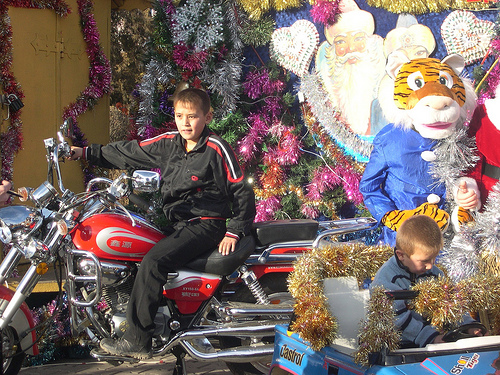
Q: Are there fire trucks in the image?
A: No, there are no fire trucks.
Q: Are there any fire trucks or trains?
A: No, there are no fire trucks or trains.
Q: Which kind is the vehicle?
A: The vehicle is a car.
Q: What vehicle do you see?
A: The vehicle is a car.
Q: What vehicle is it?
A: The vehicle is a car.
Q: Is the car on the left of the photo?
A: No, the car is on the right of the image.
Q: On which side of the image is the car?
A: The car is on the right of the image.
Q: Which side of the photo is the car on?
A: The car is on the right of the image.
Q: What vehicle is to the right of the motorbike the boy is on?
A: The vehicle is a car.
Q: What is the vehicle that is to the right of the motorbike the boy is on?
A: The vehicle is a car.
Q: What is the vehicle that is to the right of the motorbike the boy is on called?
A: The vehicle is a car.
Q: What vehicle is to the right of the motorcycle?
A: The vehicle is a car.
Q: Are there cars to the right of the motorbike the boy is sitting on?
A: Yes, there is a car to the right of the motorbike.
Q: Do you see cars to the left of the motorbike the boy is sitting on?
A: No, the car is to the right of the motorcycle.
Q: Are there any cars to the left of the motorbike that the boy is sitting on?
A: No, the car is to the right of the motorcycle.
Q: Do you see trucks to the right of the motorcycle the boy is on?
A: No, there is a car to the right of the motorbike.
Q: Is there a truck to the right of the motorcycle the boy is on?
A: No, there is a car to the right of the motorbike.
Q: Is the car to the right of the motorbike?
A: Yes, the car is to the right of the motorbike.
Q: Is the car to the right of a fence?
A: No, the car is to the right of the motorbike.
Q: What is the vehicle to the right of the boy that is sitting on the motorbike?
A: The vehicle is a car.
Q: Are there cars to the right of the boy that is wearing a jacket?
A: Yes, there is a car to the right of the boy.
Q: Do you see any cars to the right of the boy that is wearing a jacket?
A: Yes, there is a car to the right of the boy.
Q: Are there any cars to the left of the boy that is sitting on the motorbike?
A: No, the car is to the right of the boy.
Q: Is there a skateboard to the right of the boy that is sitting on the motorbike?
A: No, there is a car to the right of the boy.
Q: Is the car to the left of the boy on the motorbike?
A: No, the car is to the right of the boy.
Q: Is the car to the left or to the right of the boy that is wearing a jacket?
A: The car is to the right of the boy.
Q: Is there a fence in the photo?
A: No, there are no fences.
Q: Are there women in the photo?
A: No, there are no women.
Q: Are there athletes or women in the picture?
A: No, there are no women or athletes.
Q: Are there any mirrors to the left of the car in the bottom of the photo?
A: No, there is a boy to the left of the car.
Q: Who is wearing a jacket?
A: The boy is wearing a jacket.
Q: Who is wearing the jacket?
A: The boy is wearing a jacket.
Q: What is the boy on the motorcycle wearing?
A: The boy is wearing a jacket.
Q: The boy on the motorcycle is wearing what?
A: The boy is wearing a jacket.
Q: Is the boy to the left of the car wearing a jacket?
A: Yes, the boy is wearing a jacket.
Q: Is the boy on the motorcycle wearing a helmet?
A: No, the boy is wearing a jacket.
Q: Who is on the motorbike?
A: The boy is on the motorbike.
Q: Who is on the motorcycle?
A: The boy is on the motorbike.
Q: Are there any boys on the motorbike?
A: Yes, there is a boy on the motorbike.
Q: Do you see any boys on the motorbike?
A: Yes, there is a boy on the motorbike.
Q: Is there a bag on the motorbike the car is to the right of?
A: No, there is a boy on the motorbike.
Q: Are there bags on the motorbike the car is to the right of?
A: No, there is a boy on the motorbike.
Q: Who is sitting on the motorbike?
A: The boy is sitting on the motorbike.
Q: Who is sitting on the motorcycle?
A: The boy is sitting on the motorbike.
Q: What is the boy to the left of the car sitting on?
A: The boy is sitting on the motorbike.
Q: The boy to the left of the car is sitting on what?
A: The boy is sitting on the motorbike.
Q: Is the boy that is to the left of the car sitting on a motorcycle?
A: Yes, the boy is sitting on a motorcycle.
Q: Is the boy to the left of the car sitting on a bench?
A: No, the boy is sitting on a motorcycle.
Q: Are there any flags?
A: No, there are no flags.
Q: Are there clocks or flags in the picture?
A: No, there are no flags or clocks.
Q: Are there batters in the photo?
A: No, there are no batters.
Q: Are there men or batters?
A: No, there are no batters or men.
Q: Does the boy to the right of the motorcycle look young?
A: Yes, the boy is young.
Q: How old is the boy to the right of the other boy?
A: The boy is young.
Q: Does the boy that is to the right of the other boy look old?
A: No, the boy is young.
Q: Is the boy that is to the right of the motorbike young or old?
A: The boy is young.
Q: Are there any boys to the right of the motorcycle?
A: Yes, there is a boy to the right of the motorcycle.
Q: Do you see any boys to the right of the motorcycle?
A: Yes, there is a boy to the right of the motorcycle.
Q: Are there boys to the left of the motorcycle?
A: No, the boy is to the right of the motorcycle.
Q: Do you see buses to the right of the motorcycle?
A: No, there is a boy to the right of the motorcycle.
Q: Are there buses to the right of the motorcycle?
A: No, there is a boy to the right of the motorcycle.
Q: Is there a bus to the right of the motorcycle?
A: No, there is a boy to the right of the motorcycle.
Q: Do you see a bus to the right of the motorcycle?
A: No, there is a boy to the right of the motorcycle.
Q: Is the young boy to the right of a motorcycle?
A: Yes, the boy is to the right of a motorcycle.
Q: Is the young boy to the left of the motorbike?
A: No, the boy is to the right of the motorbike.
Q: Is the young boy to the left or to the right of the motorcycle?
A: The boy is to the right of the motorcycle.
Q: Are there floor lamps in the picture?
A: No, there are no floor lamps.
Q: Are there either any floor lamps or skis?
A: No, there are no floor lamps or skis.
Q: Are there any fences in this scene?
A: No, there are no fences.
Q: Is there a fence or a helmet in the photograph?
A: No, there are no fences or helmets.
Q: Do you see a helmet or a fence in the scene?
A: No, there are no fences or helmets.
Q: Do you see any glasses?
A: No, there are no glasses.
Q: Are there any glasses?
A: No, there are no glasses.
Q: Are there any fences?
A: No, there are no fences.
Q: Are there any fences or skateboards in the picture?
A: No, there are no fences or skateboards.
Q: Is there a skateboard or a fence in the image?
A: No, there are no fences or skateboards.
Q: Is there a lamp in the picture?
A: No, there are no lamps.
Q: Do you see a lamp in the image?
A: No, there are no lamps.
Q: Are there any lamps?
A: No, there are no lamps.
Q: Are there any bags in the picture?
A: No, there are no bags.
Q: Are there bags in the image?
A: No, there are no bags.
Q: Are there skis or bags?
A: No, there are no bags or skis.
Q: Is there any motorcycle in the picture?
A: Yes, there is a motorcycle.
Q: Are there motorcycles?
A: Yes, there is a motorcycle.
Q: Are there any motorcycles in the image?
A: Yes, there is a motorcycle.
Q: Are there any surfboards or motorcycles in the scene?
A: Yes, there is a motorcycle.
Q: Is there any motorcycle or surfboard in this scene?
A: Yes, there is a motorcycle.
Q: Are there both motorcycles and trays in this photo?
A: No, there is a motorcycle but no trays.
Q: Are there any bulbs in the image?
A: No, there are no bulbs.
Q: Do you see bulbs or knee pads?
A: No, there are no bulbs or knee pads.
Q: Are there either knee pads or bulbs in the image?
A: No, there are no bulbs or knee pads.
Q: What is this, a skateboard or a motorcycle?
A: This is a motorcycle.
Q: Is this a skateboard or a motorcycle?
A: This is a motorcycle.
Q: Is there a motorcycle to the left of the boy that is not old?
A: Yes, there is a motorcycle to the left of the boy.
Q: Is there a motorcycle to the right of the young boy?
A: No, the motorcycle is to the left of the boy.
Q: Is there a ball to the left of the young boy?
A: No, there is a motorcycle to the left of the boy.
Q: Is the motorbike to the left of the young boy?
A: Yes, the motorbike is to the left of the boy.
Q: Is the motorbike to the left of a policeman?
A: No, the motorbike is to the left of the boy.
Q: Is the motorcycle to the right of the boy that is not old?
A: No, the motorcycle is to the left of the boy.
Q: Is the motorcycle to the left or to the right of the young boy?
A: The motorcycle is to the left of the boy.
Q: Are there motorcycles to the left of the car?
A: Yes, there is a motorcycle to the left of the car.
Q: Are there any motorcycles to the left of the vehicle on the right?
A: Yes, there is a motorcycle to the left of the car.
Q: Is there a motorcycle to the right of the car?
A: No, the motorcycle is to the left of the car.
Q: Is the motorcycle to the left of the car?
A: Yes, the motorcycle is to the left of the car.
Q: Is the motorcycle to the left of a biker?
A: No, the motorcycle is to the left of the car.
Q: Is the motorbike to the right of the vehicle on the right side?
A: No, the motorbike is to the left of the car.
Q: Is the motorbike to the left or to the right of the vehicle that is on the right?
A: The motorbike is to the left of the car.